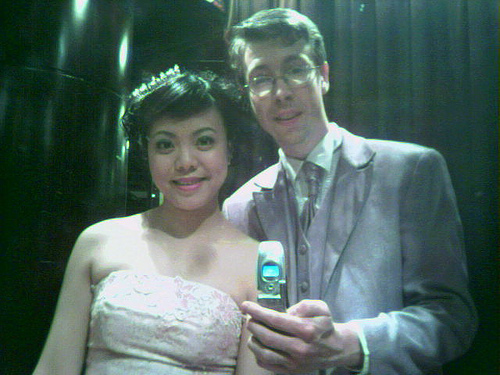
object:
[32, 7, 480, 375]
couple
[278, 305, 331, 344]
walking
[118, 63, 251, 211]
head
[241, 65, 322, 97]
glasses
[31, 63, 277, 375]
people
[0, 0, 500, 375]
mirror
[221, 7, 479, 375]
man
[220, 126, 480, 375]
coat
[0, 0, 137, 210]
wall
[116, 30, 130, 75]
light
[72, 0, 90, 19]
light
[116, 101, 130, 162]
light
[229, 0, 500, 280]
curtain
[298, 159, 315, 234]
tie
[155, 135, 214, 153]
eyes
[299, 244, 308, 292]
buttons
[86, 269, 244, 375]
dress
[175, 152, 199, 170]
nose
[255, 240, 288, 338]
cell phone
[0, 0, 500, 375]
picture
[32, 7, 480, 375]
selfie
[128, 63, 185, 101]
crown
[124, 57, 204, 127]
tiarra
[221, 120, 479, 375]
suit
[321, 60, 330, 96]
ear